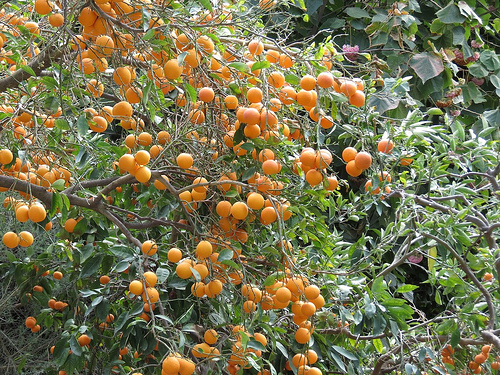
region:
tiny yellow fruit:
[165, 241, 187, 256]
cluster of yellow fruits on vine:
[106, 148, 168, 190]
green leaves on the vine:
[325, 340, 365, 367]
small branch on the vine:
[335, 318, 445, 348]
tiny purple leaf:
[342, 38, 369, 58]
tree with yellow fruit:
[58, 7, 441, 323]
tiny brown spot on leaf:
[44, 200, 72, 212]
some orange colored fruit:
[61, 30, 431, 347]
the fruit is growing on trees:
[20, 15, 410, 345]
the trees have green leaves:
[30, 25, 450, 345]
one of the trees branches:
[0, 145, 95, 245]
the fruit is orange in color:
[25, 11, 366, 331]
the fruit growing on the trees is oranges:
[7, 17, 412, 368]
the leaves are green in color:
[321, 10, 491, 135]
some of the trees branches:
[418, 139, 479, 319]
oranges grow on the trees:
[81, 17, 342, 273]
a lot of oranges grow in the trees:
[20, 8, 335, 357]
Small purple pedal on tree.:
[403, 248, 425, 266]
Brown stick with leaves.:
[411, 218, 481, 325]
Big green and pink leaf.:
[402, 47, 452, 105]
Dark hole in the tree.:
[403, 260, 439, 320]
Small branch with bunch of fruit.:
[1, 163, 236, 257]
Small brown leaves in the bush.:
[385, 5, 411, 17]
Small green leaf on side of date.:
[193, 345, 204, 353]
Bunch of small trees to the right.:
[441, 162, 477, 297]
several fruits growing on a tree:
[83, 27, 310, 299]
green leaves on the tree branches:
[413, 158, 484, 323]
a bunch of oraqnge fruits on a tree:
[155, 346, 199, 373]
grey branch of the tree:
[38, 168, 150, 235]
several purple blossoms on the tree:
[347, 12, 479, 112]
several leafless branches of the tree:
[78, 0, 277, 102]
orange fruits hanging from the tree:
[13, 200, 48, 225]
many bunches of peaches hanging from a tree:
[1, 25, 393, 355]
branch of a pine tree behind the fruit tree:
[1, 224, 58, 374]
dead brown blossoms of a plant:
[426, 74, 469, 117]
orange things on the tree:
[71, 87, 283, 242]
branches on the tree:
[128, 133, 210, 233]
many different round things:
[141, 144, 333, 290]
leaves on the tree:
[349, 195, 438, 288]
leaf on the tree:
[388, 38, 460, 103]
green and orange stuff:
[63, 26, 465, 276]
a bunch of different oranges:
[234, 75, 301, 146]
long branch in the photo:
[14, 169, 87, 210]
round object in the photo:
[272, 283, 299, 305]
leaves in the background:
[402, 263, 437, 311]